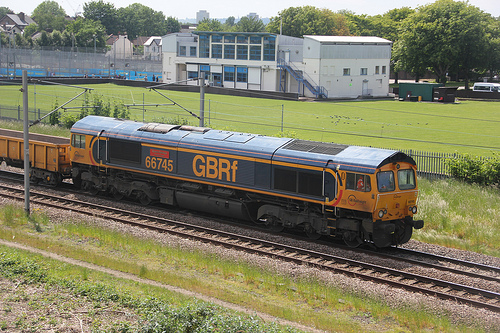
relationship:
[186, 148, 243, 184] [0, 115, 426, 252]
lettering are on train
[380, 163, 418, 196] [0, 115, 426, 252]
windshield on train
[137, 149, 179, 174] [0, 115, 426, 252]
number are on train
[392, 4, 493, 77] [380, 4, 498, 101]
leaves are on tree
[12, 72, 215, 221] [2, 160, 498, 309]
poles over tracks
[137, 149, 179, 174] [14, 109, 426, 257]
number on side of train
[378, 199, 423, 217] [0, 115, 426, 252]
lights are in front of train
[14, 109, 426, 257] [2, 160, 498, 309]
train traveling down tracks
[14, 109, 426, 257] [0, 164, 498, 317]
train on track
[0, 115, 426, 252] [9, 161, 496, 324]
train next to tracks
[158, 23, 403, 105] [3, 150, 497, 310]
building beyond train tracks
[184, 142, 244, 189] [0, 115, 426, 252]
lettering on train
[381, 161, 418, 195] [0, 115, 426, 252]
window in front of train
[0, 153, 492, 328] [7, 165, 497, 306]
gravel around train tracks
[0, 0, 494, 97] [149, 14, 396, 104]
trees are behind building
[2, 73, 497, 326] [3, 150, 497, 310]
grass around train tracks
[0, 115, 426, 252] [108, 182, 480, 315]
train on tracks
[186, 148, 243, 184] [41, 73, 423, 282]
lettering on train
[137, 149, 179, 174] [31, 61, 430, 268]
number on train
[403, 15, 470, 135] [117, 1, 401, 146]
trees behind building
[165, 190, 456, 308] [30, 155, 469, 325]
tracks on ground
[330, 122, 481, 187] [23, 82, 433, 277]
fence behind train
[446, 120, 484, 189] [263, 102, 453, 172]
bushes next to fence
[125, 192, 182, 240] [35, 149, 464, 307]
plank on track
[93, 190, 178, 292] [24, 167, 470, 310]
plank on track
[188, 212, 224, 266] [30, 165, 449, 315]
plank on track